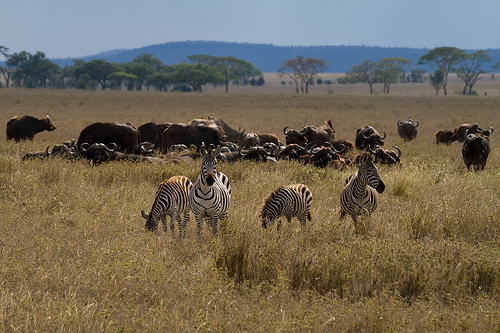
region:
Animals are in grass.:
[18, 102, 483, 265]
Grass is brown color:
[233, 237, 409, 293]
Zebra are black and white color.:
[144, 156, 348, 225]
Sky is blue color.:
[39, 17, 197, 42]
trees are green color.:
[23, 58, 229, 88]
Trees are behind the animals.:
[20, 48, 293, 109]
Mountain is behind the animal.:
[90, 21, 373, 89]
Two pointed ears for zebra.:
[196, 139, 234, 167]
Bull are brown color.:
[57, 123, 394, 169]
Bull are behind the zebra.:
[70, 113, 355, 170]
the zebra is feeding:
[129, 166, 196, 243]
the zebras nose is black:
[193, 146, 227, 187]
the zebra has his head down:
[253, 178, 321, 242]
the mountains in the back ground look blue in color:
[3, 38, 498, 71]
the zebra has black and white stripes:
[335, 154, 397, 234]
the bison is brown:
[6, 110, 58, 145]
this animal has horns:
[361, 125, 388, 142]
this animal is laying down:
[76, 137, 155, 178]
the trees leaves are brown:
[283, 51, 328, 96]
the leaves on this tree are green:
[104, 71, 138, 91]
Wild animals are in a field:
[15, 57, 495, 288]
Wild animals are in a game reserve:
[25, 40, 490, 323]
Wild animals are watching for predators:
[25, 80, 485, 320]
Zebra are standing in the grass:
[16, 36, 477, 326]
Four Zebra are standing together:
[78, 111, 458, 291]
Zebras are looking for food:
[75, 98, 463, 294]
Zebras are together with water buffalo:
[45, 85, 482, 317]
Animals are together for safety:
[21, 70, 487, 301]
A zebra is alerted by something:
[187, 140, 232, 231]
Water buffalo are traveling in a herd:
[5, 102, 190, 163]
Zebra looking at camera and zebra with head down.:
[142, 147, 231, 235]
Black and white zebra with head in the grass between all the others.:
[259, 183, 313, 228]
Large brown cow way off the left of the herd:
[5, 112, 55, 142]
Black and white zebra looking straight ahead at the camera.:
[190, 141, 232, 236]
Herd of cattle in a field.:
[6, 114, 493, 168]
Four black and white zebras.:
[141, 143, 387, 233]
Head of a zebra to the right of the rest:
[356, 150, 386, 196]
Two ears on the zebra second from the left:
[198, 142, 222, 156]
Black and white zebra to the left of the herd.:
[140, 175, 195, 232]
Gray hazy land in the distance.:
[44, 36, 499, 73]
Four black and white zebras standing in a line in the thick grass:
[108, 149, 413, 261]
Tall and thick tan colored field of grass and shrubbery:
[74, 230, 471, 311]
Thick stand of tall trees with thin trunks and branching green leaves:
[41, 54, 266, 96]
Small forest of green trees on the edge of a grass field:
[16, 46, 263, 100]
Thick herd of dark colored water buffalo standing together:
[82, 106, 347, 164]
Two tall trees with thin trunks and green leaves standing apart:
[405, 41, 493, 100]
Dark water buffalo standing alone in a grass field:
[3, 102, 67, 137]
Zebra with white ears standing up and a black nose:
[196, 134, 221, 190]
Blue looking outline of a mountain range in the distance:
[128, 23, 399, 83]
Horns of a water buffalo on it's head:
[373, 128, 394, 144]